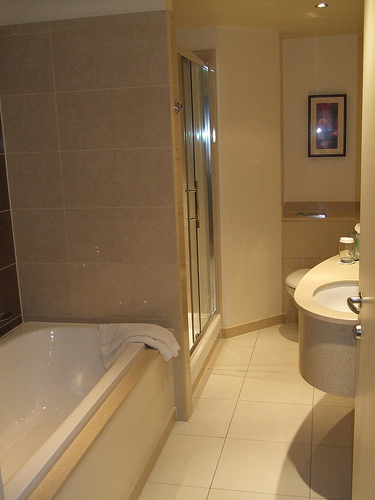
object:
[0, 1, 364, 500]
bathroom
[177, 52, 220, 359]
shower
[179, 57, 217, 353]
door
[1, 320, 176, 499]
bathtub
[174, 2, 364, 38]
ceiling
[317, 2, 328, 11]
lighting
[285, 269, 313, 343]
toilet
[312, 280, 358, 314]
sink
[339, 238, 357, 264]
jar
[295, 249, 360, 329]
counter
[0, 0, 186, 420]
wall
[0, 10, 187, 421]
tile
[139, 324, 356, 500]
floor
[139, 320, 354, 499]
tile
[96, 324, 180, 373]
towel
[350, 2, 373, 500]
door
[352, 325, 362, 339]
lock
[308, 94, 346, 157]
picture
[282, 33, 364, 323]
wall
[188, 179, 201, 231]
handle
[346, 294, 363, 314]
handle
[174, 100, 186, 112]
hook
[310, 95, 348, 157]
frame